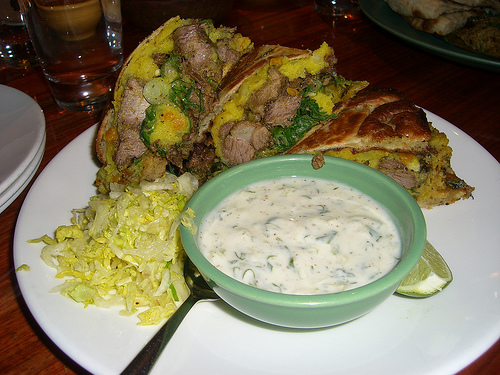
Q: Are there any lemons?
A: Yes, there is a lemon.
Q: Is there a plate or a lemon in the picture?
A: Yes, there is a lemon.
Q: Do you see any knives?
A: No, there are no knives.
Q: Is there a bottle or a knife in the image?
A: No, there are no knives or bottles.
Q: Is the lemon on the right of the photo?
A: Yes, the lemon is on the right of the image.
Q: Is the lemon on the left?
A: No, the lemon is on the right of the image.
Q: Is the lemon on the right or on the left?
A: The lemon is on the right of the image.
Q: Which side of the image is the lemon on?
A: The lemon is on the right of the image.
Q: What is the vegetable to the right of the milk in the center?
A: The vegetable is a lemon.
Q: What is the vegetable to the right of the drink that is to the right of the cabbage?
A: The vegetable is a lemon.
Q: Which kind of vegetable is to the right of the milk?
A: The vegetable is a lemon.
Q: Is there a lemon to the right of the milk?
A: Yes, there is a lemon to the right of the milk.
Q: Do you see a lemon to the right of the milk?
A: Yes, there is a lemon to the right of the milk.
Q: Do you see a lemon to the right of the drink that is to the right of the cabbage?
A: Yes, there is a lemon to the right of the milk.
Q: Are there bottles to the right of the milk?
A: No, there is a lemon to the right of the milk.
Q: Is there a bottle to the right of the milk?
A: No, there is a lemon to the right of the milk.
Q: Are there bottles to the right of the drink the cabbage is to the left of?
A: No, there is a lemon to the right of the milk.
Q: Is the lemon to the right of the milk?
A: Yes, the lemon is to the right of the milk.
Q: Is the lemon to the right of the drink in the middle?
A: Yes, the lemon is to the right of the milk.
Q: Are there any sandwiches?
A: Yes, there is a sandwich.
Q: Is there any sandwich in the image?
A: Yes, there is a sandwich.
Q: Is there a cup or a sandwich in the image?
A: Yes, there is a sandwich.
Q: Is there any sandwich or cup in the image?
A: Yes, there is a sandwich.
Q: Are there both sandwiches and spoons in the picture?
A: Yes, there are both a sandwich and a spoon.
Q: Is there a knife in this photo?
A: No, there are no knives.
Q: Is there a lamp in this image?
A: No, there are no lamps.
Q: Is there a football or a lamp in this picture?
A: No, there are no lamps or footballs.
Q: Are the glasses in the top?
A: Yes, the glasses are in the top of the image.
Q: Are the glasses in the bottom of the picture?
A: No, the glasses are in the top of the image.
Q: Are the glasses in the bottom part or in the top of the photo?
A: The glasses are in the top of the image.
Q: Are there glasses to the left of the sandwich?
A: Yes, there are glasses to the left of the sandwich.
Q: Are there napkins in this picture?
A: No, there are no napkins.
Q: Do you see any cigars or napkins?
A: No, there are no napkins or cigars.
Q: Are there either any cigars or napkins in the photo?
A: No, there are no napkins or cigars.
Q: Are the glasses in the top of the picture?
A: Yes, the glasses are in the top of the image.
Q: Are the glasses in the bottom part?
A: No, the glasses are in the top of the image.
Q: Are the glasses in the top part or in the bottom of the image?
A: The glasses are in the top of the image.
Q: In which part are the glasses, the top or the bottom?
A: The glasses are in the top of the image.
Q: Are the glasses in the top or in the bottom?
A: The glasses are in the top of the image.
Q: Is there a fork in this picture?
A: No, there are no forks.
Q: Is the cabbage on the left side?
A: Yes, the cabbage is on the left of the image.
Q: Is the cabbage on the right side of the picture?
A: No, the cabbage is on the left of the image.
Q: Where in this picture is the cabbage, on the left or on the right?
A: The cabbage is on the left of the image.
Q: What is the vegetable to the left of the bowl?
A: The vegetable is a cabbage.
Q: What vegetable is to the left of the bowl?
A: The vegetable is a cabbage.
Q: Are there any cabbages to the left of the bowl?
A: Yes, there is a cabbage to the left of the bowl.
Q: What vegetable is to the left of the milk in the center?
A: The vegetable is a cabbage.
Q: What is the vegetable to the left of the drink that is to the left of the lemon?
A: The vegetable is a cabbage.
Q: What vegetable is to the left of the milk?
A: The vegetable is a cabbage.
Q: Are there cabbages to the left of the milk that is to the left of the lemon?
A: Yes, there is a cabbage to the left of the milk.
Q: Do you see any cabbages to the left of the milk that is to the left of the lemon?
A: Yes, there is a cabbage to the left of the milk.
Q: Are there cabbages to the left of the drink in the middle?
A: Yes, there is a cabbage to the left of the milk.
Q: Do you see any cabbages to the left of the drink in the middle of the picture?
A: Yes, there is a cabbage to the left of the milk.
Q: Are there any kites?
A: No, there are no kites.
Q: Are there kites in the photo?
A: No, there are no kites.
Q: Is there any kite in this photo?
A: No, there are no kites.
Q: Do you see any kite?
A: No, there are no kites.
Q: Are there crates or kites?
A: No, there are no kites or crates.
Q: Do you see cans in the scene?
A: No, there are no cans.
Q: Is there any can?
A: No, there are no cans.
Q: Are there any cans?
A: No, there are no cans.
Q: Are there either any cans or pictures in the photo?
A: No, there are no cans or pictures.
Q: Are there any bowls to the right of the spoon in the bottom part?
A: Yes, there is a bowl to the right of the spoon.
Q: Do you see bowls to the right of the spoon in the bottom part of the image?
A: Yes, there is a bowl to the right of the spoon.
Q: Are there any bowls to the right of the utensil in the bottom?
A: Yes, there is a bowl to the right of the spoon.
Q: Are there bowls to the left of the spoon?
A: No, the bowl is to the right of the spoon.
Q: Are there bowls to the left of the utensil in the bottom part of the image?
A: No, the bowl is to the right of the spoon.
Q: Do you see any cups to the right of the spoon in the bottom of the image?
A: No, there is a bowl to the right of the spoon.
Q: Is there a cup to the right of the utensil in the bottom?
A: No, there is a bowl to the right of the spoon.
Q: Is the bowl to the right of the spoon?
A: Yes, the bowl is to the right of the spoon.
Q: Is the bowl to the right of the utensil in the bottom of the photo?
A: Yes, the bowl is to the right of the spoon.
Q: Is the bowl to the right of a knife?
A: No, the bowl is to the right of the spoon.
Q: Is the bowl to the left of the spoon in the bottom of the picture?
A: No, the bowl is to the right of the spoon.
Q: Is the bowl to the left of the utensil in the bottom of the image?
A: No, the bowl is to the right of the spoon.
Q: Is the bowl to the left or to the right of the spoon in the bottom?
A: The bowl is to the right of the spoon.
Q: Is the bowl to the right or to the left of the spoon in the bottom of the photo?
A: The bowl is to the right of the spoon.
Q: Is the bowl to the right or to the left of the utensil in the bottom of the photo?
A: The bowl is to the right of the spoon.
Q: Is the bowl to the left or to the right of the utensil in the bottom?
A: The bowl is to the right of the spoon.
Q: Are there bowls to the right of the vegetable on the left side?
A: Yes, there is a bowl to the right of the cabbage.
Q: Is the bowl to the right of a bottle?
A: No, the bowl is to the right of the cabbage.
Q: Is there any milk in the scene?
A: Yes, there is milk.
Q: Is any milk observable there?
A: Yes, there is milk.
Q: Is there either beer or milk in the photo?
A: Yes, there is milk.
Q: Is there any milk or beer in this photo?
A: Yes, there is milk.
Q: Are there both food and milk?
A: Yes, there are both milk and food.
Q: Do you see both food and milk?
A: Yes, there are both milk and food.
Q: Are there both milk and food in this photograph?
A: Yes, there are both milk and food.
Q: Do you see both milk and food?
A: Yes, there are both milk and food.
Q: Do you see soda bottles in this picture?
A: No, there are no soda bottles.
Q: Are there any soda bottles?
A: No, there are no soda bottles.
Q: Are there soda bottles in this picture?
A: No, there are no soda bottles.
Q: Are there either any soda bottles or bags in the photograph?
A: No, there are no soda bottles or bags.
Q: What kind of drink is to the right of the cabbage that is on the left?
A: The drink is milk.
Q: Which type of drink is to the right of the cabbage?
A: The drink is milk.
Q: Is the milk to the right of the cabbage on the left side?
A: Yes, the milk is to the right of the cabbage.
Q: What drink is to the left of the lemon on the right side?
A: The drink is milk.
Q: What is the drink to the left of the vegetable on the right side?
A: The drink is milk.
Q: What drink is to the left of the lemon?
A: The drink is milk.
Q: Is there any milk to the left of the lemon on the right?
A: Yes, there is milk to the left of the lemon.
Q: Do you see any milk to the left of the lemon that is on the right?
A: Yes, there is milk to the left of the lemon.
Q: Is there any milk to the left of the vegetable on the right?
A: Yes, there is milk to the left of the lemon.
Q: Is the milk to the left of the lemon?
A: Yes, the milk is to the left of the lemon.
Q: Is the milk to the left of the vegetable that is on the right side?
A: Yes, the milk is to the left of the lemon.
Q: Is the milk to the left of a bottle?
A: No, the milk is to the left of the lemon.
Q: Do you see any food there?
A: Yes, there is food.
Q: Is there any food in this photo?
A: Yes, there is food.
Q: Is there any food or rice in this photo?
A: Yes, there is food.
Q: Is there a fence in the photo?
A: No, there are no fences.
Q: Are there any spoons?
A: Yes, there is a spoon.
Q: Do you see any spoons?
A: Yes, there is a spoon.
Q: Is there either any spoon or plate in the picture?
A: Yes, there is a spoon.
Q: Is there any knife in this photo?
A: No, there are no knives.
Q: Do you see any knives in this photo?
A: No, there are no knives.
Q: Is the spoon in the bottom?
A: Yes, the spoon is in the bottom of the image.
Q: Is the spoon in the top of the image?
A: No, the spoon is in the bottom of the image.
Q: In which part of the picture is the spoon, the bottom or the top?
A: The spoon is in the bottom of the image.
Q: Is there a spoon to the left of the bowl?
A: Yes, there is a spoon to the left of the bowl.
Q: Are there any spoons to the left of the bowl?
A: Yes, there is a spoon to the left of the bowl.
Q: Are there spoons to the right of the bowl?
A: No, the spoon is to the left of the bowl.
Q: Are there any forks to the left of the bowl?
A: No, there is a spoon to the left of the bowl.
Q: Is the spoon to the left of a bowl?
A: Yes, the spoon is to the left of a bowl.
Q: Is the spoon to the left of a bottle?
A: No, the spoon is to the left of a bowl.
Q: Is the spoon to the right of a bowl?
A: No, the spoon is to the left of a bowl.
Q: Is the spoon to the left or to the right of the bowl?
A: The spoon is to the left of the bowl.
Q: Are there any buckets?
A: No, there are no buckets.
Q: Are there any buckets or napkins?
A: No, there are no buckets or napkins.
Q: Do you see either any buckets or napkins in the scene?
A: No, there are no buckets or napkins.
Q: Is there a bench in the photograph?
A: No, there are no benches.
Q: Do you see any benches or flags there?
A: No, there are no benches or flags.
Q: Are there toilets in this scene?
A: No, there are no toilets.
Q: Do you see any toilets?
A: No, there are no toilets.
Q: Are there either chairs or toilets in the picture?
A: No, there are no toilets or chairs.